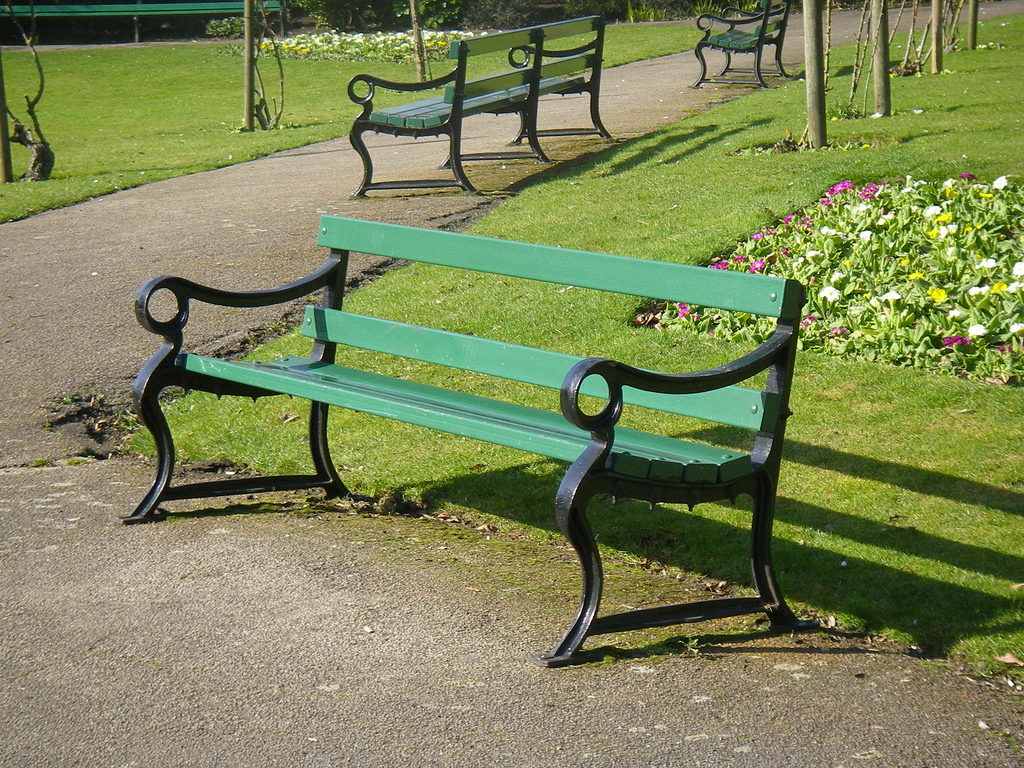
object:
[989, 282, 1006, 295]
flowers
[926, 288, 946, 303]
flowers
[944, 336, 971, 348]
flowers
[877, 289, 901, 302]
flowers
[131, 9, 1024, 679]
grass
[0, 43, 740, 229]
grass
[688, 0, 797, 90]
bench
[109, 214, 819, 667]
bench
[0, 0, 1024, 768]
sidewalk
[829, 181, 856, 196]
flower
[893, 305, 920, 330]
flower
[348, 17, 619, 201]
bench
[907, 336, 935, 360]
flower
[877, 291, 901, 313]
flower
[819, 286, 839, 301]
flower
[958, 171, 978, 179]
flower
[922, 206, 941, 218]
flower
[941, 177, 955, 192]
flower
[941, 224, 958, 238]
flower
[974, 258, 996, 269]
flower